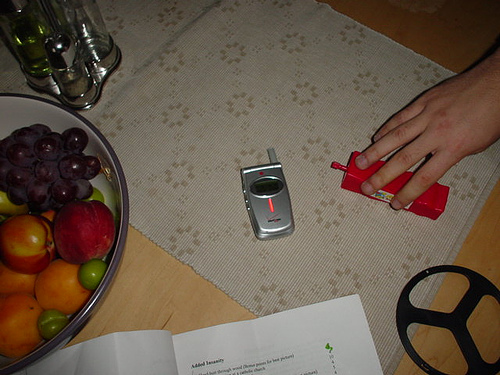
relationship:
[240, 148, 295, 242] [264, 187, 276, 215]
cell phone has red light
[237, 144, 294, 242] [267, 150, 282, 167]
cell phone has antenna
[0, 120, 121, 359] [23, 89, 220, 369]
fruit in bowl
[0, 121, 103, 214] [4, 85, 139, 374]
grapes in bowl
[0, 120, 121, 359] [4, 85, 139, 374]
fruit in bowl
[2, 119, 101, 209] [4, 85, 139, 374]
grapes in bowl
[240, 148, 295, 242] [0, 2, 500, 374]
cell phone on table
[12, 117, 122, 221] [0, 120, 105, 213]
cluster of grapes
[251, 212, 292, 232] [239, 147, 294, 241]
verizon printed on cellphone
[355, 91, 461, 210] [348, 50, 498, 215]
fingers on hand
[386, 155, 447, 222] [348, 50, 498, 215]
fingers on hand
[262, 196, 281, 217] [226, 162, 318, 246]
light on cellphone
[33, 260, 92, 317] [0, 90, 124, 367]
orange in bowl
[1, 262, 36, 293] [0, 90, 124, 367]
orange in bowl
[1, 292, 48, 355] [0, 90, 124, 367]
orange in bowl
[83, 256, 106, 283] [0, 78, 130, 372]
lime in bowl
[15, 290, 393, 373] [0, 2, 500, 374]
book on table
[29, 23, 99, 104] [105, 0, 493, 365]
shaker on table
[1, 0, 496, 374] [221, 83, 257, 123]
placemat with design